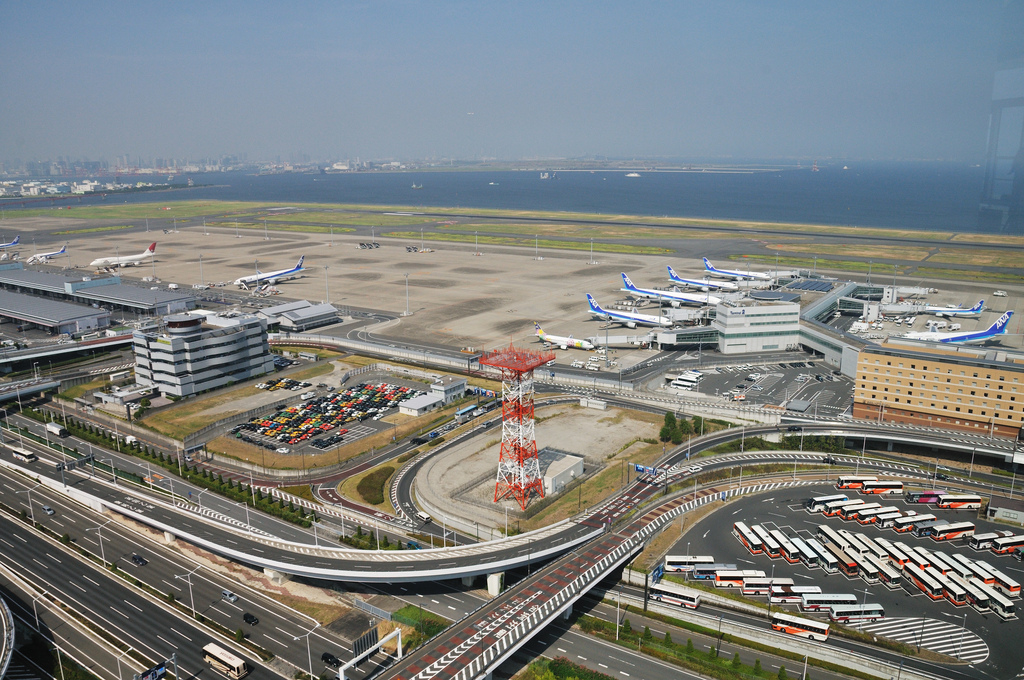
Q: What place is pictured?
A: It is an airport.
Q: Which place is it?
A: It is an airport.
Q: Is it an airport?
A: Yes, it is an airport.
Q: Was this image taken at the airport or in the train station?
A: It was taken at the airport.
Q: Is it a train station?
A: No, it is an airport.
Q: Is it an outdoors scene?
A: Yes, it is outdoors.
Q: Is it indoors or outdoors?
A: It is outdoors.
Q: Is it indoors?
A: No, it is outdoors.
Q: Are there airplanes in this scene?
A: Yes, there is an airplane.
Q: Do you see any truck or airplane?
A: Yes, there is an airplane.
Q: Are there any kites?
A: No, there are no kites.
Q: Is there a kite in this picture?
A: No, there are no kites.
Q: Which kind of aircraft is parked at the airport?
A: The aircraft is an airplane.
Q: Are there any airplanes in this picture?
A: Yes, there is an airplane.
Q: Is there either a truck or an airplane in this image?
A: Yes, there is an airplane.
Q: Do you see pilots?
A: No, there are no pilots.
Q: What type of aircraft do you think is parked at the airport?
A: The aircraft is an airplane.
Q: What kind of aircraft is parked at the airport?
A: The aircraft is an airplane.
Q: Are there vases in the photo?
A: No, there are no vases.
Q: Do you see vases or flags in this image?
A: No, there are no vases or flags.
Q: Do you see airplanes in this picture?
A: Yes, there is an airplane.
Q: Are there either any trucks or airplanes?
A: Yes, there is an airplane.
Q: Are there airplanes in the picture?
A: Yes, there is an airplane.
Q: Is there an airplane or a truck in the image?
A: Yes, there is an airplane.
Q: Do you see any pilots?
A: No, there are no pilots.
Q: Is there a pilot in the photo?
A: No, there are no pilots.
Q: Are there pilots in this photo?
A: No, there are no pilots.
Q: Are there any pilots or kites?
A: No, there are no pilots or kites.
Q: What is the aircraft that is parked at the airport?
A: The aircraft is an airplane.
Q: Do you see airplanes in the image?
A: Yes, there is an airplane.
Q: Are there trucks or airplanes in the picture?
A: Yes, there is an airplane.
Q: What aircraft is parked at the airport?
A: The aircraft is an airplane.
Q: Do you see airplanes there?
A: Yes, there is an airplane.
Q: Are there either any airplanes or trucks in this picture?
A: Yes, there is an airplane.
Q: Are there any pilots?
A: No, there are no pilots.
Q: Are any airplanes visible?
A: Yes, there is an airplane.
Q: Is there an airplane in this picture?
A: Yes, there is an airplane.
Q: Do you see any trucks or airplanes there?
A: Yes, there is an airplane.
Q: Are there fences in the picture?
A: No, there are no fences.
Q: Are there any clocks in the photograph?
A: No, there are no clocks.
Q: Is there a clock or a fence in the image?
A: No, there are no clocks or fences.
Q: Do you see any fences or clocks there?
A: No, there are no clocks or fences.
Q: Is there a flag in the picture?
A: No, there are no flags.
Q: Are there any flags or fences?
A: No, there are no flags or fences.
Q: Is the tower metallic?
A: Yes, the tower is metallic.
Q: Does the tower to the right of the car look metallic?
A: Yes, the tower is metallic.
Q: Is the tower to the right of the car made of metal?
A: Yes, the tower is made of metal.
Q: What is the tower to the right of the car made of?
A: The tower is made of metal.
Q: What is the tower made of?
A: The tower is made of metal.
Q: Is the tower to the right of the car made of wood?
A: No, the tower is made of metal.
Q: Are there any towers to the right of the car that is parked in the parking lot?
A: Yes, there is a tower to the right of the car.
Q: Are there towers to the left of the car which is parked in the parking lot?
A: No, the tower is to the right of the car.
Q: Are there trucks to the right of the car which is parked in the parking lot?
A: No, there is a tower to the right of the car.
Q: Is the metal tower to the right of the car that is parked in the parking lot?
A: Yes, the tower is to the right of the car.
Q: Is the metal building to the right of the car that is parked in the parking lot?
A: Yes, the tower is to the right of the car.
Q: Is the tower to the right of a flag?
A: No, the tower is to the right of the car.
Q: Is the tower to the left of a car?
A: No, the tower is to the right of a car.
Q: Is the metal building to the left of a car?
A: No, the tower is to the right of a car.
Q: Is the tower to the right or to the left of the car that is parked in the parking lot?
A: The tower is to the right of the car.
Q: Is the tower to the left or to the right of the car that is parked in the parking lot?
A: The tower is to the right of the car.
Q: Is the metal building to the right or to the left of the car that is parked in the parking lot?
A: The tower is to the right of the car.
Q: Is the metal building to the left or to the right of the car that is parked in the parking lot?
A: The tower is to the right of the car.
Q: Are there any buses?
A: Yes, there is a bus.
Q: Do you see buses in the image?
A: Yes, there is a bus.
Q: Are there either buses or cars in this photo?
A: Yes, there is a bus.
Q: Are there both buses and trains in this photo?
A: No, there is a bus but no trains.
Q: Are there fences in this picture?
A: No, there are no fences.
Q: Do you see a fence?
A: No, there are no fences.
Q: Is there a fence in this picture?
A: No, there are no fences.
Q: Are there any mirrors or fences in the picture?
A: No, there are no fences or mirrors.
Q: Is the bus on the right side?
A: Yes, the bus is on the right of the image.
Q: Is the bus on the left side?
A: No, the bus is on the right of the image.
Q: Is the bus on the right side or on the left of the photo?
A: The bus is on the right of the image.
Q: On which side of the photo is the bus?
A: The bus is on the right of the image.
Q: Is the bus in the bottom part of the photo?
A: Yes, the bus is in the bottom of the image.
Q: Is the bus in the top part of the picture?
A: No, the bus is in the bottom of the image.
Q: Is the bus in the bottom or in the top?
A: The bus is in the bottom of the image.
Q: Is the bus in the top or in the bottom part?
A: The bus is in the bottom of the image.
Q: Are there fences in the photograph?
A: No, there are no fences.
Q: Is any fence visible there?
A: No, there are no fences.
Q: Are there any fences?
A: No, there are no fences.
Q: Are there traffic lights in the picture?
A: No, there are no traffic lights.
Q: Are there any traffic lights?
A: No, there are no traffic lights.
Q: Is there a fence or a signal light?
A: No, there are no traffic lights or fences.